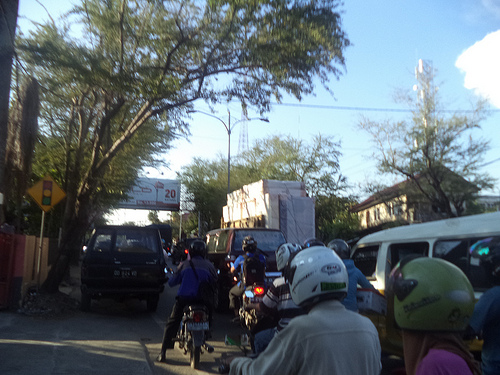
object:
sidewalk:
[0, 302, 154, 375]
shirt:
[259, 276, 308, 338]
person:
[155, 240, 219, 362]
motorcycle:
[164, 267, 222, 370]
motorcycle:
[227, 255, 265, 355]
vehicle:
[80, 225, 168, 312]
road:
[0, 248, 249, 375]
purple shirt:
[416, 348, 472, 375]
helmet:
[188, 240, 207, 259]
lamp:
[260, 118, 270, 122]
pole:
[227, 135, 230, 193]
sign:
[26, 173, 67, 212]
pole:
[35, 211, 45, 293]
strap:
[189, 259, 201, 283]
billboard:
[118, 177, 180, 211]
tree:
[352, 59, 500, 223]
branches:
[356, 111, 444, 211]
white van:
[350, 210, 500, 297]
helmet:
[288, 246, 349, 306]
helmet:
[388, 256, 475, 334]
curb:
[160, 297, 223, 375]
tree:
[0, 0, 354, 295]